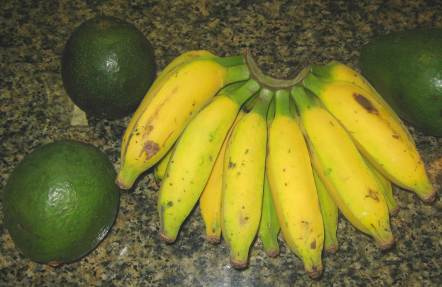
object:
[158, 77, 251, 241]
banana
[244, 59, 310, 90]
core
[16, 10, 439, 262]
table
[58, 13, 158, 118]
avocado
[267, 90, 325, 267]
banana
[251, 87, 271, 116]
stem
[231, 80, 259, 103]
stem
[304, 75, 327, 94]
stem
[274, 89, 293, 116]
stem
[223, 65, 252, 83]
stem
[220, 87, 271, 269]
banana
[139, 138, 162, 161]
spot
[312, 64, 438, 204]
banana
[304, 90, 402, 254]
banana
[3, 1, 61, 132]
counter top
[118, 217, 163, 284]
counter top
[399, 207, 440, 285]
counter top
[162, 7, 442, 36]
counter top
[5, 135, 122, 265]
fruit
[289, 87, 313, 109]
stem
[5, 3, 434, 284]
counter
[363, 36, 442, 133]
fruit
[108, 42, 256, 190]
bananas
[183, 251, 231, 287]
reflection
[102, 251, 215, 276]
countertop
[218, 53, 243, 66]
stalk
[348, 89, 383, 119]
patch